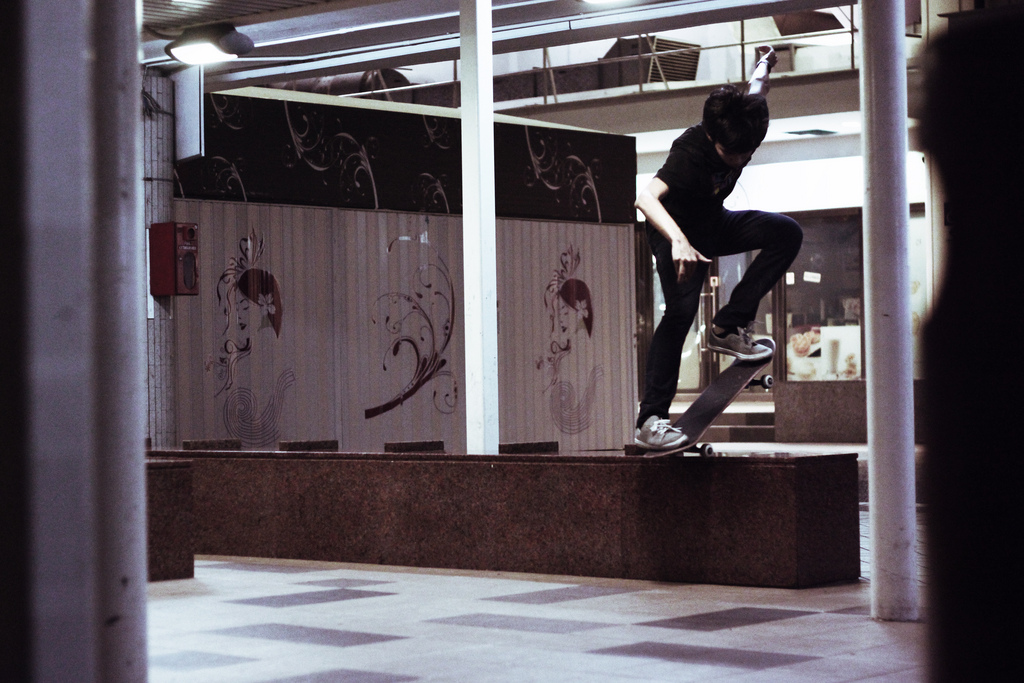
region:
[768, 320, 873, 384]
a window on a building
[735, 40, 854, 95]
a window on a building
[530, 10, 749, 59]
a window on a building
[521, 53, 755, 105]
a window on a building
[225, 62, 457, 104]
a window on a building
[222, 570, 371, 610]
a tile in a floor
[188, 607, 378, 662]
a tile in a floor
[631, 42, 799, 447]
Person in black doing a trick on a skateboard.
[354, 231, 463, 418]
Black flourish artwork on striped wall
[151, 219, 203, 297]
Speaker attached to the wall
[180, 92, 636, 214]
White flourishes on black wall trim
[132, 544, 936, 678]
Black and white rectangle patterned flooring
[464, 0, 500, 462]
White wooden post in the middle of the room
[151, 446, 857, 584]
Low bench-type surface being used by skateboarder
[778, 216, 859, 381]
Window with food and drink posters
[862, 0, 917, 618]
White round pole at the end of the bench.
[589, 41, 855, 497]
man on a skateboard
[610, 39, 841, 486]
man doing a trick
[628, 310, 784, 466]
the skateboard is black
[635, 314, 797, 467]
the skateboard is tilted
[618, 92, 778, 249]
man wearing a black shirt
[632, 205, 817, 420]
man wearing black pants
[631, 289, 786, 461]
man wearing white shoes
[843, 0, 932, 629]
white pole on the side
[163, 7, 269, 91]
light on the side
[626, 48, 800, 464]
guy on a skate board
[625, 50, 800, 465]
guy wearing a black shirt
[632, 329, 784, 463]
black skateboard with white wheels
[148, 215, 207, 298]
red box fixture on a wall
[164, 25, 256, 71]
light hanging from the ceiling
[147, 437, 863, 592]
a stone marble fixture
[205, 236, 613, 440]
two images of a women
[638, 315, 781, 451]
a pair of grey sneakers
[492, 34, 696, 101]
a metal air vent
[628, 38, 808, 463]
person doing trick on skateboard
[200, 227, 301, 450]
painting of woman on wall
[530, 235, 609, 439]
painting of woman on wall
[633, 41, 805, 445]
skater wearing black pants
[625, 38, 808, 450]
skater wearing black shirt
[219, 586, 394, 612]
black tile on floor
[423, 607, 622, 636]
black tile on floor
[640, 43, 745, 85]
glass window on the building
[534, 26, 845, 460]
Person on a skateboard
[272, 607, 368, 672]
tile is black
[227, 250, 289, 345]
a design on the wall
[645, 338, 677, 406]
the pants are black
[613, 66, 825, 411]
a person skating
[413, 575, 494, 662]
the tile on the floor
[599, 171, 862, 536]
a person on a skateboard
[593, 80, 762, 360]
a person skateboarding inside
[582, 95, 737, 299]
a person with hair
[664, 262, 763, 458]
a person wearing shoes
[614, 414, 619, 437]
a shoe on the skatebaord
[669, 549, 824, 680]
tile on the floor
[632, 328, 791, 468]
a skateboard with black and white wheels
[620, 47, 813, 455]
a guy on a skateboard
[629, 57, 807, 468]
a guy wearing a black shirt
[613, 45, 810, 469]
a guy wearing black pants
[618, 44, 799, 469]
a guy wearing grey sneakers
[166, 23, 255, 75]
a light fixture on the ceiling